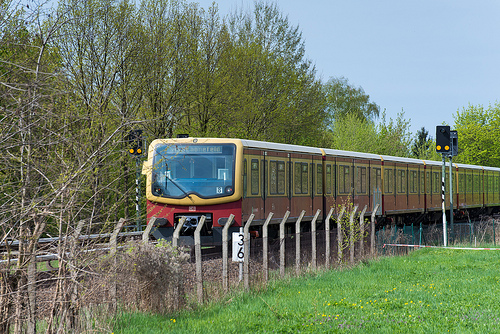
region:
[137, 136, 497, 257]
Yellow and red train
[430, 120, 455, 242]
Light signal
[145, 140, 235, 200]
Front window of the train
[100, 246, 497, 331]
Green grassland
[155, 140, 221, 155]
Digital message board of the train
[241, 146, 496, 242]
Left side of the train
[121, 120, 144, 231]
Light signal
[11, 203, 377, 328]
Fence separating grass land and train tracks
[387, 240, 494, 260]
Strip of a sidewalk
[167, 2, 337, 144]
Tall green tree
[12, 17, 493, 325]
Train traveling through rural area.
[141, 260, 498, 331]
Green grass to right of train.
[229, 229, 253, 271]
The number 36 in black.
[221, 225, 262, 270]
Square white sign mounted on fence.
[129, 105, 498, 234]
A red and yellow train.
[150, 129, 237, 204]
Large windshield on engine.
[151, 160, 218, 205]
Windshield wiper on engine.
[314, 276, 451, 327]
Small yellow flower in grass.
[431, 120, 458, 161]
A railroad light with yellow lights.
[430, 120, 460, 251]
Grey pole supporting railroad light.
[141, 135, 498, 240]
a yellow and red train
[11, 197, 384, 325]
a wooden fence by the tracks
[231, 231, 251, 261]
a number 36 by the tracks.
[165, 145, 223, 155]
the train's destination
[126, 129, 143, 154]
yellow caution lights to left of train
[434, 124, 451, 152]
yellow caution lights to right of train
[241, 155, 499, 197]
a row of windows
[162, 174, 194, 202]
the train's windshield wiper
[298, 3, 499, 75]
the clear blue sky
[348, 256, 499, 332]
a green field of grass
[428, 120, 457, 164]
two yellow train lights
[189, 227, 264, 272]
36 is written on a sign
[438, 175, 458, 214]
three black stripes onthe pole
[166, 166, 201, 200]
windshield wiper of the train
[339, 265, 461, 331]
yellow flowers in the grass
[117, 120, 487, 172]
two train light sets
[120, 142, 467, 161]
four yellow lights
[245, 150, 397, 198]
windows on the train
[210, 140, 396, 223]
train is red and yellow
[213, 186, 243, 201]
8 is on the front of train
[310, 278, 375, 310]
green grass on the ground.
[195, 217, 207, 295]
wooden post near the grass.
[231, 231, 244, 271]
black numbers on white sign.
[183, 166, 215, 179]
windshield on the train.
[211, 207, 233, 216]
red paint on the train.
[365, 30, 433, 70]
blue sky above the trees.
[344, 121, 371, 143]
leaves on the tree.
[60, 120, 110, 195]
bare limbs on tree.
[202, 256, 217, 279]
pebbles near the tracks.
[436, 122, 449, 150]
light on a pole.